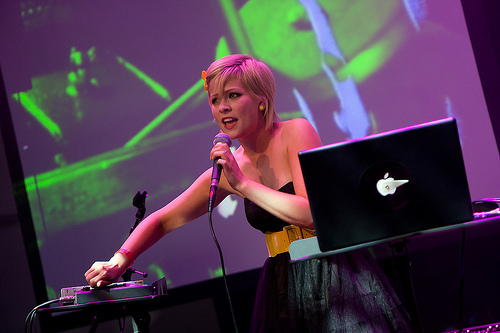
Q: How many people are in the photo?
A: One.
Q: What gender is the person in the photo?
A: Female.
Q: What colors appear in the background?
A: Purple, green, and blue.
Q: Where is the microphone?
A: In the woman's left hand.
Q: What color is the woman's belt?
A: Gold.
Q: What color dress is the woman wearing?
A: Black.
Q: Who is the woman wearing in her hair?
A: A bow.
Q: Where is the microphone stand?
A: To the left of the woman's right arm.